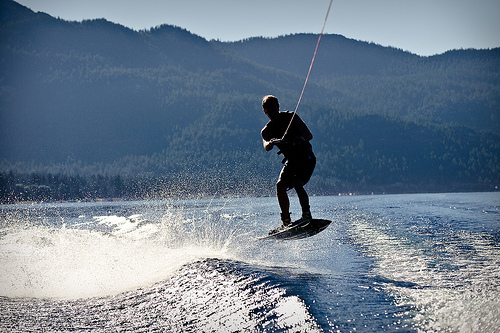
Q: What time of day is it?
A: It is daytime.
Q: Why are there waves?
A: From the boat.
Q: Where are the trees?
A: Behind the man.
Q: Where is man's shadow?
A: Below him.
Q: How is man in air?
A: From going over wave.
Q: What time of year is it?
A: Summer.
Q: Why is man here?
A: To have fun.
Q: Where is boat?
A: In front of man.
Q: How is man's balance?
A: Good.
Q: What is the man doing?
A: Waterboarding.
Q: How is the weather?
A: Sunny.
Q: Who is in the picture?
A: A man.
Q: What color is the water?
A: Blue.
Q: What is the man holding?
A: A rope.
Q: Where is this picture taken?
A: A lake.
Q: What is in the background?
A: Hills.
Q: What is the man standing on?
A: A snowboard.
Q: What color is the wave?
A: White.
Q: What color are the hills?
A: Green.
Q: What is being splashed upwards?
A: Water beads.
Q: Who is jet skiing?
A: The man.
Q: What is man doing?
A: Surfing in ocean.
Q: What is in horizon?
A: A hill.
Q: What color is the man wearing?
A: Black.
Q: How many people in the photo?
A: One.